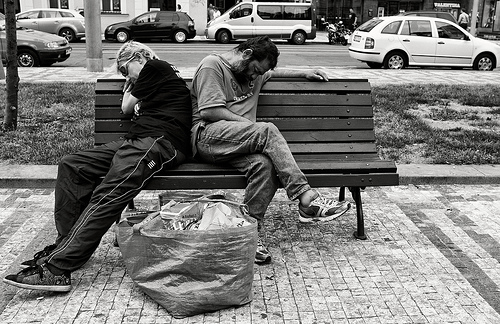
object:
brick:
[283, 312, 299, 320]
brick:
[313, 268, 330, 278]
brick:
[344, 277, 362, 288]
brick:
[98, 290, 117, 301]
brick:
[428, 299, 452, 314]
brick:
[420, 286, 437, 293]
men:
[3, 40, 192, 292]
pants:
[55, 137, 185, 270]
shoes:
[299, 189, 352, 223]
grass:
[0, 80, 500, 167]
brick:
[385, 302, 407, 316]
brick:
[279, 297, 298, 311]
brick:
[396, 240, 409, 246]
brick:
[124, 308, 141, 317]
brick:
[441, 227, 461, 241]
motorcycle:
[321, 18, 352, 47]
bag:
[115, 198, 258, 320]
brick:
[354, 296, 376, 317]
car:
[204, 2, 317, 45]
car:
[15, 8, 85, 42]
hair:
[116, 40, 160, 75]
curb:
[0, 65, 499, 83]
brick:
[387, 281, 403, 288]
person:
[457, 8, 469, 30]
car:
[348, 16, 499, 71]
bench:
[94, 78, 400, 240]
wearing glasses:
[118, 56, 136, 78]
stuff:
[159, 199, 251, 230]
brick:
[446, 243, 462, 251]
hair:
[234, 35, 280, 70]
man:
[191, 36, 352, 264]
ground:
[0, 163, 499, 323]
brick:
[335, 261, 355, 278]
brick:
[324, 261, 343, 278]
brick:
[360, 281, 385, 303]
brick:
[290, 278, 311, 301]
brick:
[399, 298, 422, 314]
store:
[366, 4, 475, 39]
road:
[44, 31, 371, 66]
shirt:
[124, 59, 193, 155]